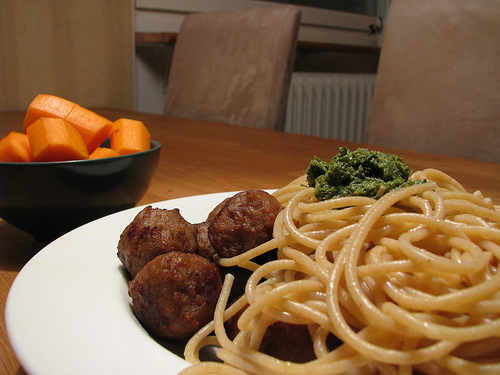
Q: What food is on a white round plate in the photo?
A: Meat, pasta and kale.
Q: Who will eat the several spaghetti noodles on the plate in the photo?
A: A person order the food.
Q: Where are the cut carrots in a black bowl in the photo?
A: Left of plate.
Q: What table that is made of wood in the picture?
A: Table food is on.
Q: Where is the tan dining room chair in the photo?
A: Behind the food.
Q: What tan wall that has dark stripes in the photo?
A: Far left.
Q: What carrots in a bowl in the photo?
A: Front of chairs.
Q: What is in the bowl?
A: Carrots.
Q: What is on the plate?
A: Spaghetti and meatballs.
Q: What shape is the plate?
A: Round.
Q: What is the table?
A: Wood.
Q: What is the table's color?
A: Brown.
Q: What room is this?
A: Kitchen.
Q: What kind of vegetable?
A: Broccoli.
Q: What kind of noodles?
A: Spaghetti.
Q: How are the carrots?
A: Sliced.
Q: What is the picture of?
A: Food.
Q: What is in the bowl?
A: Carrots.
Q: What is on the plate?
A: Noodles.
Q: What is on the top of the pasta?
A: Green food.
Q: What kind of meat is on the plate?
A: Meatballs.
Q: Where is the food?
A: On the plate.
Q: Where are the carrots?
A: In the bowl.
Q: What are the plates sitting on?
A: A table.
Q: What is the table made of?
A: Wood.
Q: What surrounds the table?
A: Chairs.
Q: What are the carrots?
A: Sliced.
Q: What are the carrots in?
A: Small bowl.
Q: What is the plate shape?
A: Round.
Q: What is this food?
A: Vegetable.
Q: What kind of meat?
A: Meatball.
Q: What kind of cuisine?
A: Italian.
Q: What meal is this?
A: Spaghetti and meatballs.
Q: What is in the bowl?
A: Carrots.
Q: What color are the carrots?
A: Orange.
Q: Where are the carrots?
A: In the bowl.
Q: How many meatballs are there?
A: Three.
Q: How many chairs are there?
A: Two.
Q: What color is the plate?
A: White.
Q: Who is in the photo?
A: Nobody.